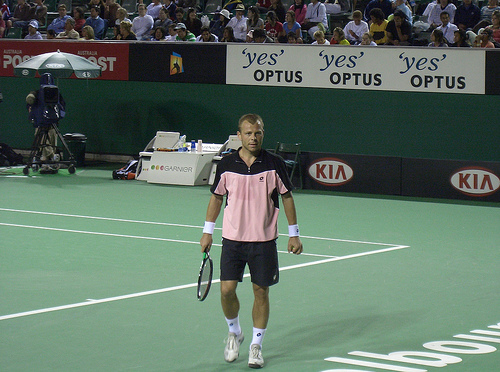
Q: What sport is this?
A: Tennis.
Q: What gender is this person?
A: Male.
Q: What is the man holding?
A: Racket.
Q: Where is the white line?
A: On the court.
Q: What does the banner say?
A: Yes.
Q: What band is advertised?
A: KIA.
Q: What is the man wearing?
A: A pink and black shirt.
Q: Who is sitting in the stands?
A: Several people.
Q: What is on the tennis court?
A: White markings.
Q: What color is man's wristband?
A: White.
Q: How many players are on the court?
A: 1.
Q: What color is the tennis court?
A: White and green.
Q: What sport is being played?
A: Tennis.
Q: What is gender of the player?
A: Male.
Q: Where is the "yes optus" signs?
A: On stands.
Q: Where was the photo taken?
A: Tennis court.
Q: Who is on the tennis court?
A: Tennis player.